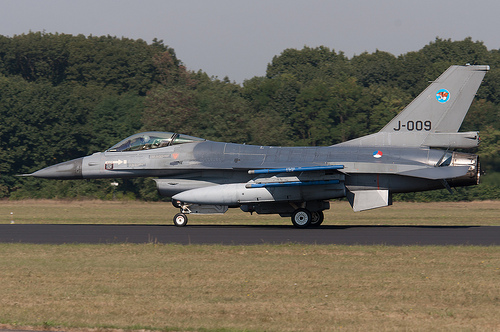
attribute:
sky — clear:
[188, 2, 405, 45]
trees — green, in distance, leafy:
[32, 22, 380, 122]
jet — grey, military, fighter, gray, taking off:
[20, 58, 471, 239]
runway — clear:
[22, 211, 474, 246]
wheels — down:
[169, 208, 329, 239]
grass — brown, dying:
[8, 242, 489, 312]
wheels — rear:
[288, 197, 325, 234]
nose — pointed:
[0, 137, 57, 200]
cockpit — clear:
[111, 118, 184, 154]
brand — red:
[350, 141, 386, 169]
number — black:
[388, 116, 437, 128]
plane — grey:
[15, 43, 482, 237]